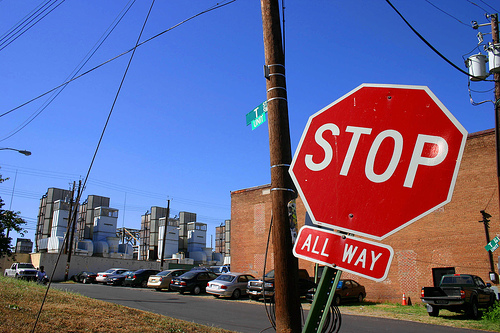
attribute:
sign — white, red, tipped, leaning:
[290, 84, 470, 240]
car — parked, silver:
[206, 272, 260, 298]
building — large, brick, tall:
[229, 126, 498, 306]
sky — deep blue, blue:
[0, 1, 499, 253]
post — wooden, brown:
[262, 1, 302, 333]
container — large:
[157, 217, 177, 224]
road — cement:
[46, 280, 488, 332]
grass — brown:
[1, 281, 240, 331]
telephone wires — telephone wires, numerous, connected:
[0, 1, 236, 116]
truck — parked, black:
[4, 260, 36, 280]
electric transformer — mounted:
[467, 54, 487, 79]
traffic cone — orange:
[402, 294, 408, 306]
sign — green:
[245, 100, 266, 131]